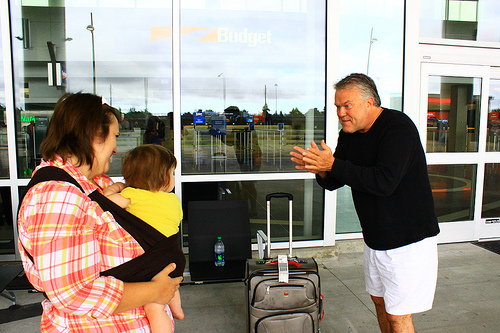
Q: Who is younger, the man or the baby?
A: The baby is younger than the man.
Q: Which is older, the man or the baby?
A: The man is older than the baby.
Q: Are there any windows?
A: Yes, there is a window.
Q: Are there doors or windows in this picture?
A: Yes, there is a window.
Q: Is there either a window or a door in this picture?
A: Yes, there is a window.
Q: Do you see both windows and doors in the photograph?
A: Yes, there are both a window and a door.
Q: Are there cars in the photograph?
A: No, there are no cars.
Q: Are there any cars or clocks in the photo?
A: No, there are no cars or clocks.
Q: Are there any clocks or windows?
A: Yes, there is a window.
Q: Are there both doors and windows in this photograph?
A: Yes, there are both a window and a door.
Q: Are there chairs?
A: No, there are no chairs.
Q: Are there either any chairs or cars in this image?
A: No, there are no chairs or cars.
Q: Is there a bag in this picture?
A: Yes, there is a bag.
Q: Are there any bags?
A: Yes, there is a bag.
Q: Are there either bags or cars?
A: Yes, there is a bag.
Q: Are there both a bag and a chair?
A: No, there is a bag but no chairs.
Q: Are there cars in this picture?
A: No, there are no cars.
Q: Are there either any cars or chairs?
A: No, there are no cars or chairs.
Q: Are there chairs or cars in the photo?
A: No, there are no cars or chairs.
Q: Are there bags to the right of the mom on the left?
A: Yes, there is a bag to the right of the mom.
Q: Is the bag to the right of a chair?
A: No, the bag is to the right of a mother.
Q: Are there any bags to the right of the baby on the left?
A: Yes, there is a bag to the right of the baby.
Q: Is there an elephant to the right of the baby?
A: No, there is a bag to the right of the baby.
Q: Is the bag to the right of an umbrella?
A: No, the bag is to the right of the baby.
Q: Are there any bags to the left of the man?
A: Yes, there is a bag to the left of the man.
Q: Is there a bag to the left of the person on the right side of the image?
A: Yes, there is a bag to the left of the man.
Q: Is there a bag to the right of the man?
A: No, the bag is to the left of the man.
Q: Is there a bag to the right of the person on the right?
A: No, the bag is to the left of the man.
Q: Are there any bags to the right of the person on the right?
A: No, the bag is to the left of the man.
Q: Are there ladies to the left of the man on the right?
A: No, there is a bag to the left of the man.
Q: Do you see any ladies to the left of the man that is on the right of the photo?
A: No, there is a bag to the left of the man.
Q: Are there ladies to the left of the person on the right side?
A: No, there is a bag to the left of the man.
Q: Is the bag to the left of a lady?
A: No, the bag is to the left of a man.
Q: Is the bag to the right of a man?
A: No, the bag is to the left of a man.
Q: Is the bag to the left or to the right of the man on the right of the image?
A: The bag is to the left of the man.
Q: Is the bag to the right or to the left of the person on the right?
A: The bag is to the left of the man.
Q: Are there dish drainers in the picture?
A: No, there are no dish drainers.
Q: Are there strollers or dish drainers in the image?
A: No, there are no dish drainers or strollers.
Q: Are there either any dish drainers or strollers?
A: No, there are no dish drainers or strollers.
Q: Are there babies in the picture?
A: Yes, there is a baby.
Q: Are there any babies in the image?
A: Yes, there is a baby.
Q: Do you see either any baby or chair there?
A: Yes, there is a baby.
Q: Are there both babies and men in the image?
A: Yes, there are both a baby and men.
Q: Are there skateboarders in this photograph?
A: No, there are no skateboarders.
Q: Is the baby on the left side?
A: Yes, the baby is on the left of the image.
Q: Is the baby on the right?
A: No, the baby is on the left of the image.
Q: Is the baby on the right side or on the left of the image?
A: The baby is on the left of the image.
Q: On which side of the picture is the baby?
A: The baby is on the left of the image.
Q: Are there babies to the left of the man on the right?
A: Yes, there is a baby to the left of the man.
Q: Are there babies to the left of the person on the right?
A: Yes, there is a baby to the left of the man.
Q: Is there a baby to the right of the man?
A: No, the baby is to the left of the man.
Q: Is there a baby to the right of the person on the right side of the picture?
A: No, the baby is to the left of the man.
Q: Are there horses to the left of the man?
A: No, there is a baby to the left of the man.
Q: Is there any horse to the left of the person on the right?
A: No, there is a baby to the left of the man.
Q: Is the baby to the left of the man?
A: Yes, the baby is to the left of the man.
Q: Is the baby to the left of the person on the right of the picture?
A: Yes, the baby is to the left of the man.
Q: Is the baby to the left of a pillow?
A: No, the baby is to the left of the man.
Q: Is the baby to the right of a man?
A: No, the baby is to the left of a man.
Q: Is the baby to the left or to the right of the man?
A: The baby is to the left of the man.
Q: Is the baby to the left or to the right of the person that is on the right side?
A: The baby is to the left of the man.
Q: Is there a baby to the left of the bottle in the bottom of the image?
A: Yes, there is a baby to the left of the bottle.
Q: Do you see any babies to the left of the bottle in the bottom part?
A: Yes, there is a baby to the left of the bottle.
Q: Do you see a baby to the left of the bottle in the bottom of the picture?
A: Yes, there is a baby to the left of the bottle.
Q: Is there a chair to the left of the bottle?
A: No, there is a baby to the left of the bottle.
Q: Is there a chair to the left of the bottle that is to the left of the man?
A: No, there is a baby to the left of the bottle.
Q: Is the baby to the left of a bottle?
A: Yes, the baby is to the left of a bottle.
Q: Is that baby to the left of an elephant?
A: No, the baby is to the left of a bottle.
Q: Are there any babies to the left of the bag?
A: Yes, there is a baby to the left of the bag.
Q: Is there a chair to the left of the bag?
A: No, there is a baby to the left of the bag.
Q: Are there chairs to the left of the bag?
A: No, there is a baby to the left of the bag.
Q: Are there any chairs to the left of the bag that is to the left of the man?
A: No, there is a baby to the left of the bag.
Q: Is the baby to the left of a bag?
A: Yes, the baby is to the left of a bag.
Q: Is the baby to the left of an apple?
A: No, the baby is to the left of a bag.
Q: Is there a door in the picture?
A: Yes, there is a door.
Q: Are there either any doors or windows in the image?
A: Yes, there is a door.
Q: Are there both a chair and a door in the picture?
A: No, there is a door but no chairs.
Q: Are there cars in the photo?
A: No, there are no cars.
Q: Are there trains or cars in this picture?
A: No, there are no cars or trains.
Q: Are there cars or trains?
A: No, there are no cars or trains.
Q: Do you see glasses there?
A: No, there are no glasses.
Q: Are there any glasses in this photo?
A: No, there are no glasses.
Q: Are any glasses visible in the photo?
A: No, there are no glasses.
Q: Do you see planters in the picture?
A: No, there are no planters.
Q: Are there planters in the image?
A: No, there are no planters.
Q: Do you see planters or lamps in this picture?
A: No, there are no planters or lamps.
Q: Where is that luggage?
A: The luggage is on the ground.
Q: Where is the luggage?
A: The luggage is on the ground.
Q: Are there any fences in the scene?
A: No, there are no fences.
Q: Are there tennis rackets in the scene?
A: No, there are no tennis rackets.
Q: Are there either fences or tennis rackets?
A: No, there are no tennis rackets or fences.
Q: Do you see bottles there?
A: Yes, there is a bottle.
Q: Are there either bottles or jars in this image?
A: Yes, there is a bottle.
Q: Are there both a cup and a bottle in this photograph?
A: No, there is a bottle but no cups.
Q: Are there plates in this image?
A: No, there are no plates.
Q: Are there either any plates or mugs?
A: No, there are no plates or mugs.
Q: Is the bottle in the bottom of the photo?
A: Yes, the bottle is in the bottom of the image.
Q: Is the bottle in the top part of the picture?
A: No, the bottle is in the bottom of the image.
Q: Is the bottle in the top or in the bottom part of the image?
A: The bottle is in the bottom of the image.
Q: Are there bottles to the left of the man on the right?
A: Yes, there is a bottle to the left of the man.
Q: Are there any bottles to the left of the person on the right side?
A: Yes, there is a bottle to the left of the man.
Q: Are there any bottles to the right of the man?
A: No, the bottle is to the left of the man.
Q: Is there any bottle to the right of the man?
A: No, the bottle is to the left of the man.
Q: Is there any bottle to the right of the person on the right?
A: No, the bottle is to the left of the man.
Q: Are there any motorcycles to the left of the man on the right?
A: No, there is a bottle to the left of the man.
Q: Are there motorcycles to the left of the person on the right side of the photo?
A: No, there is a bottle to the left of the man.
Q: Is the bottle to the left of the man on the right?
A: Yes, the bottle is to the left of the man.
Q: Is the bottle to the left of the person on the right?
A: Yes, the bottle is to the left of the man.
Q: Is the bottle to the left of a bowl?
A: No, the bottle is to the left of the man.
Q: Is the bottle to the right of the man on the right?
A: No, the bottle is to the left of the man.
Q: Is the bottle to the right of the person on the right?
A: No, the bottle is to the left of the man.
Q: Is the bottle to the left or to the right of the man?
A: The bottle is to the left of the man.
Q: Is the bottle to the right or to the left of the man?
A: The bottle is to the left of the man.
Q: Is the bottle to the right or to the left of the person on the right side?
A: The bottle is to the left of the man.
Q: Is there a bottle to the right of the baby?
A: Yes, there is a bottle to the right of the baby.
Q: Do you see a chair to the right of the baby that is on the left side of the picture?
A: No, there is a bottle to the right of the baby.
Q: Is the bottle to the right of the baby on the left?
A: Yes, the bottle is to the right of the baby.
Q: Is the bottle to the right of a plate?
A: No, the bottle is to the right of the baby.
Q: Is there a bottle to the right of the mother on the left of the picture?
A: Yes, there is a bottle to the right of the mother.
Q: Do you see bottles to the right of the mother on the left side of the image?
A: Yes, there is a bottle to the right of the mother.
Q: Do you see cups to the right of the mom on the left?
A: No, there is a bottle to the right of the mom.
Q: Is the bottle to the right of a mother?
A: Yes, the bottle is to the right of a mother.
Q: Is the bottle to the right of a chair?
A: No, the bottle is to the right of a mother.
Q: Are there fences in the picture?
A: No, there are no fences.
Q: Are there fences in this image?
A: No, there are no fences.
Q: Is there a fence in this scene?
A: No, there are no fences.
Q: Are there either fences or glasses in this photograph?
A: No, there are no fences or glasses.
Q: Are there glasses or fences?
A: No, there are no fences or glasses.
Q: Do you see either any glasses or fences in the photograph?
A: No, there are no fences or glasses.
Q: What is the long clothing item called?
A: The clothing item is a shirt.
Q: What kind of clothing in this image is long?
A: The clothing is a shirt.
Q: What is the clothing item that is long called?
A: The clothing item is a shirt.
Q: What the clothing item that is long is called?
A: The clothing item is a shirt.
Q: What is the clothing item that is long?
A: The clothing item is a shirt.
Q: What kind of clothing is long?
A: The clothing is a shirt.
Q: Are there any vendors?
A: No, there are no vendors.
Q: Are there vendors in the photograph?
A: No, there are no vendors.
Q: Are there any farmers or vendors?
A: No, there are no vendors or farmers.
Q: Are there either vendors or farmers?
A: No, there are no vendors or farmers.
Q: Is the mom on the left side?
A: Yes, the mom is on the left of the image.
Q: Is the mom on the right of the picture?
A: No, the mom is on the left of the image.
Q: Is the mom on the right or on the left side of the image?
A: The mom is on the left of the image.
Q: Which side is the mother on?
A: The mother is on the left of the image.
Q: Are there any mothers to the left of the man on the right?
A: Yes, there is a mother to the left of the man.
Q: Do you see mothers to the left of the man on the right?
A: Yes, there is a mother to the left of the man.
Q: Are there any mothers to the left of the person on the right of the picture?
A: Yes, there is a mother to the left of the man.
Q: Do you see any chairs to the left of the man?
A: No, there is a mother to the left of the man.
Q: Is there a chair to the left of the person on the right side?
A: No, there is a mother to the left of the man.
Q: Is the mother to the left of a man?
A: Yes, the mother is to the left of a man.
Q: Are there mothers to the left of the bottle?
A: Yes, there is a mother to the left of the bottle.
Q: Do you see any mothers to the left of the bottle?
A: Yes, there is a mother to the left of the bottle.